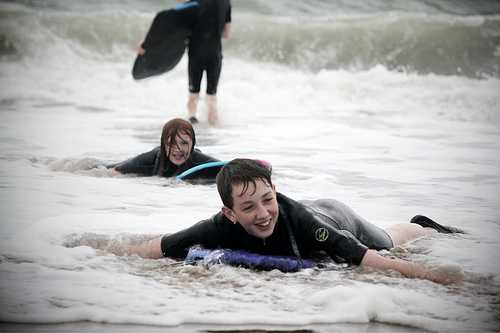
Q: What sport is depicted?
A: Bodyboarding.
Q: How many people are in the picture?
A: Three.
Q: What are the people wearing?
A: Wetsuits.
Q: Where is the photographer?
A: At the beach.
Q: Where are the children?
A: Lying in the water.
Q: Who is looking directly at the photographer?
A: A girl.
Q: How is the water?
A: Foamy.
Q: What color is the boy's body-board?
A: Blue.